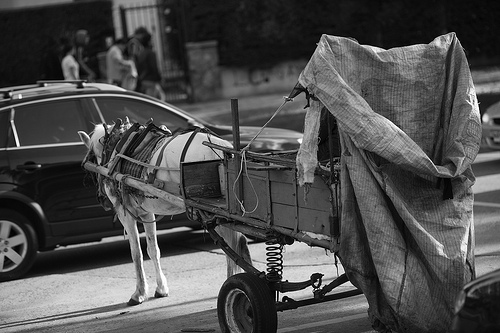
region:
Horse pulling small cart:
[73, 107, 380, 325]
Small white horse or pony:
[75, 120, 250, 305]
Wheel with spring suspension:
[212, 222, 317, 327]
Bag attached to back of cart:
[302, 22, 469, 327]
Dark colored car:
[0, 70, 310, 260]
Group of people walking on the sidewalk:
[45, 25, 170, 105]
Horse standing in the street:
[76, 113, 231, 323]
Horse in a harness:
[86, 118, 248, 308]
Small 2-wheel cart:
[213, 94, 375, 331]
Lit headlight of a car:
[477, 106, 498, 146]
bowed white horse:
[67, 114, 252, 320]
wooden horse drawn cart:
[207, 127, 337, 247]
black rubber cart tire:
[208, 266, 273, 331]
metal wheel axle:
[262, 263, 375, 314]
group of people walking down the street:
[47, 23, 187, 101]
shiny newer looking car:
[1, 74, 324, 279]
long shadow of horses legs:
[0, 299, 127, 331]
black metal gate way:
[102, 1, 204, 98]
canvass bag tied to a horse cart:
[277, 28, 484, 331]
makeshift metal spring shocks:
[242, 222, 284, 282]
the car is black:
[17, 71, 246, 269]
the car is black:
[32, 123, 209, 330]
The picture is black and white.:
[36, 33, 461, 312]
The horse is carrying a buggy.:
[73, 107, 223, 272]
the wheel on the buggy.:
[201, 255, 296, 326]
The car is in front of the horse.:
[9, 68, 327, 245]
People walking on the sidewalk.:
[58, 46, 181, 117]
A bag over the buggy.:
[301, 35, 466, 311]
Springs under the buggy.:
[255, 227, 294, 294]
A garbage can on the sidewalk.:
[181, 22, 235, 104]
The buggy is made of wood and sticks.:
[206, 123, 332, 261]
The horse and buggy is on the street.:
[86, 113, 465, 330]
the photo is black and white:
[1, 1, 499, 331]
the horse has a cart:
[172, 45, 482, 331]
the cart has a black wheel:
[208, 270, 289, 330]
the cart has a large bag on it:
[279, 21, 481, 331]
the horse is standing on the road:
[77, 99, 274, 321]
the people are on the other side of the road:
[48, 22, 175, 107]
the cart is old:
[202, 27, 479, 332]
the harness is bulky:
[98, 112, 188, 223]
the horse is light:
[78, 112, 265, 305]